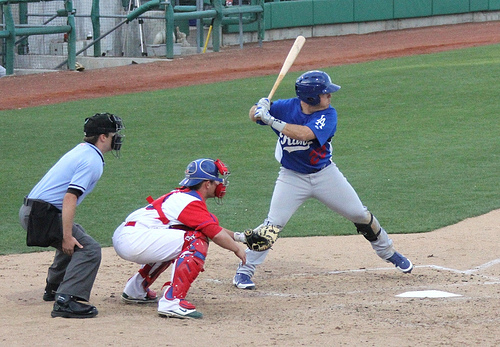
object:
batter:
[232, 70, 413, 290]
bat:
[256, 35, 306, 120]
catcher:
[112, 158, 245, 320]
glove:
[239, 224, 279, 252]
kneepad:
[172, 230, 209, 299]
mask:
[214, 158, 231, 205]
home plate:
[395, 290, 462, 298]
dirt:
[2, 204, 496, 347]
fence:
[0, 0, 263, 76]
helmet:
[295, 70, 341, 106]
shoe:
[51, 299, 98, 318]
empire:
[18, 112, 124, 318]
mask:
[112, 114, 126, 159]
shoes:
[43, 286, 57, 301]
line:
[273, 258, 500, 281]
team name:
[279, 132, 307, 146]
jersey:
[255, 98, 337, 174]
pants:
[236, 163, 395, 279]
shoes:
[233, 273, 256, 290]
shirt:
[125, 186, 223, 240]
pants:
[111, 222, 186, 312]